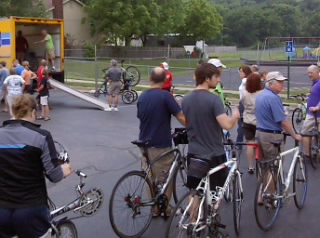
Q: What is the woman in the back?
A: This is a person.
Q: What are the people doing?
A: Riding bikes.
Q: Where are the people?
A: In the street.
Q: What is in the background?
A: A truck.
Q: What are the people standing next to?
A: Bicycles.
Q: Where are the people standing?
A: Ont he road.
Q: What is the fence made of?
A: Metal.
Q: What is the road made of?
A: Pavement.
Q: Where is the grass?
A: Around the fence.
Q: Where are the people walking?
A: On the pavement.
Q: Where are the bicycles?
A: On the pavement.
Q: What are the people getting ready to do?
A: Ride bicycles.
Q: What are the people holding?
A: Bicycles.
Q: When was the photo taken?
A: Daytime.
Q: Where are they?
A: In a parking lot.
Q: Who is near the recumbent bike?
A: Woman in the gray and black jacket.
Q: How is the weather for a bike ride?
A: Overcast.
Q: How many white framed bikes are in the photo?
A: 2.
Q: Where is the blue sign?
A: On the right.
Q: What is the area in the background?
A: Park.